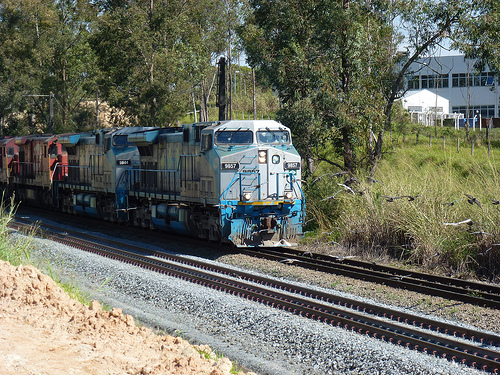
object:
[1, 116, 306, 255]
train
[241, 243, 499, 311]
tracks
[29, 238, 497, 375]
gravel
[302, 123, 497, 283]
grass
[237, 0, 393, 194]
tree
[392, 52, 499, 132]
building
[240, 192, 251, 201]
headlight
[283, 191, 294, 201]
headlight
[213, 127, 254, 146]
windshield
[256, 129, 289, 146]
windshield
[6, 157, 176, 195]
rail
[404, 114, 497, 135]
fence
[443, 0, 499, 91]
tree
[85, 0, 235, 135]
tree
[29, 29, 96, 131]
tree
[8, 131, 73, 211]
traincar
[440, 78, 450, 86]
window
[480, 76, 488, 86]
window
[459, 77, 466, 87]
window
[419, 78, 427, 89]
window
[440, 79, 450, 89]
window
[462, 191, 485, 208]
bird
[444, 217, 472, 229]
bird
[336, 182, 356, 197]
bird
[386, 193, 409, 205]
bird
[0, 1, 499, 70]
sky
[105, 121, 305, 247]
train engine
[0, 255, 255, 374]
hillside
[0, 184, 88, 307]
grass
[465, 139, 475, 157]
post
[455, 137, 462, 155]
post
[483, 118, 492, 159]
post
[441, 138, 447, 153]
post